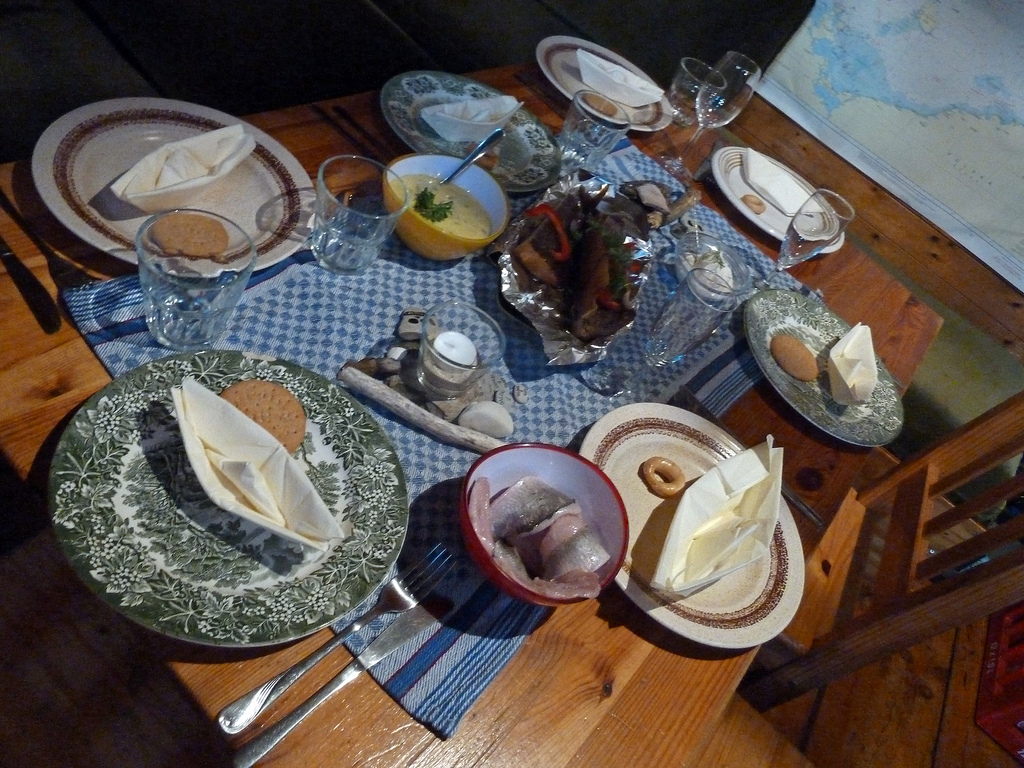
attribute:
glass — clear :
[137, 204, 254, 353]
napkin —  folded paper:
[165, 371, 344, 565]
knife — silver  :
[228, 554, 503, 766]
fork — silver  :
[206, 567, 475, 742]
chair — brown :
[737, 381, 1019, 714]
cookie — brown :
[207, 370, 313, 453]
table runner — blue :
[62, 117, 821, 731]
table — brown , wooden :
[10, 68, 947, 765]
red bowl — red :
[450, 436, 629, 621]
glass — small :
[306, 167, 398, 276]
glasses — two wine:
[665, 62, 776, 124]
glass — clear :
[369, 286, 530, 429]